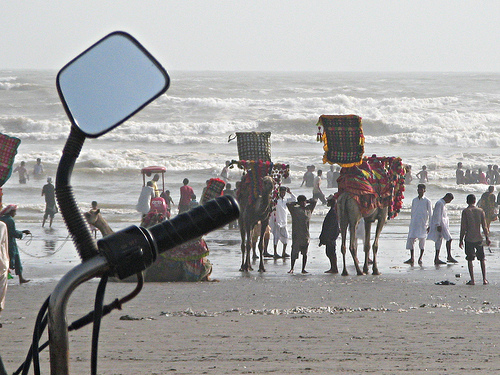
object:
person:
[316, 195, 339, 273]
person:
[269, 185, 296, 264]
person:
[427, 190, 457, 270]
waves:
[221, 95, 282, 136]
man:
[286, 195, 317, 274]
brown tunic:
[286, 202, 316, 238]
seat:
[316, 112, 368, 169]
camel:
[338, 156, 403, 280]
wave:
[260, 108, 312, 132]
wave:
[359, 117, 472, 131]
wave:
[14, 108, 64, 130]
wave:
[126, 117, 234, 131]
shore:
[399, 268, 448, 279]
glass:
[58, 34, 168, 140]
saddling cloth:
[340, 157, 403, 214]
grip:
[98, 193, 240, 280]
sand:
[388, 289, 412, 297]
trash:
[435, 278, 455, 288]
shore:
[143, 282, 220, 375]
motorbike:
[0, 28, 240, 373]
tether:
[13, 224, 82, 257]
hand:
[19, 230, 32, 245]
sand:
[246, 331, 279, 337]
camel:
[226, 167, 283, 274]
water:
[455, 67, 478, 100]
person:
[179, 176, 194, 208]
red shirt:
[177, 183, 192, 202]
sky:
[98, 72, 129, 91]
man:
[402, 184, 430, 267]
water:
[211, 79, 246, 93]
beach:
[285, 343, 377, 372]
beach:
[424, 333, 497, 373]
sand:
[212, 280, 239, 294]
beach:
[271, 291, 367, 333]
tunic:
[406, 199, 429, 223]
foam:
[204, 90, 299, 110]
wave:
[78, 144, 158, 172]